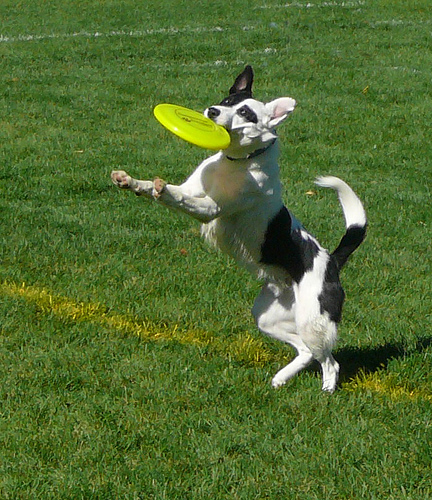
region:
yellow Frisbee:
[143, 77, 226, 149]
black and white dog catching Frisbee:
[145, 59, 391, 374]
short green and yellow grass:
[41, 381, 90, 430]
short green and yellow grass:
[298, 399, 351, 464]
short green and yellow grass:
[370, 442, 397, 469]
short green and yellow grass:
[39, 287, 79, 356]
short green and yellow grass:
[93, 266, 127, 324]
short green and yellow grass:
[149, 308, 194, 372]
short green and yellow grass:
[46, 113, 80, 156]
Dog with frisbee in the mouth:
[163, 67, 369, 389]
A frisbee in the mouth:
[159, 110, 197, 122]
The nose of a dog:
[208, 108, 216, 115]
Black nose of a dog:
[209, 109, 217, 116]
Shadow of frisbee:
[209, 169, 240, 189]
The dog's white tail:
[344, 195, 354, 211]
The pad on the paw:
[156, 180, 161, 189]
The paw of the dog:
[113, 171, 127, 185]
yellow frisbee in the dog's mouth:
[154, 99, 231, 153]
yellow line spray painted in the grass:
[0, 280, 421, 405]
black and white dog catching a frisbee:
[101, 60, 374, 398]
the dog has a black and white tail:
[313, 165, 365, 266]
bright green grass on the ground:
[0, 2, 428, 497]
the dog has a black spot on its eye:
[233, 102, 261, 124]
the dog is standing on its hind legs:
[111, 68, 380, 399]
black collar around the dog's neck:
[213, 133, 280, 159]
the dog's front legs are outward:
[111, 160, 225, 224]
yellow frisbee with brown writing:
[152, 99, 233, 154]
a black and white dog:
[109, 63, 368, 395]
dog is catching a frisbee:
[109, 63, 368, 395]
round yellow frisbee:
[152, 102, 230, 150]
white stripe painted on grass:
[0, 16, 427, 46]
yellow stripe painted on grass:
[2, 277, 428, 407]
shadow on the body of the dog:
[199, 154, 311, 324]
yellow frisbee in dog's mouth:
[109, 64, 368, 394]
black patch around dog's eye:
[234, 103, 259, 124]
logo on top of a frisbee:
[173, 105, 217, 132]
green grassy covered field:
[2, 0, 429, 496]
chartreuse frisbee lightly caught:
[145, 97, 237, 154]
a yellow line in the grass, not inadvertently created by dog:
[0, 253, 429, 417]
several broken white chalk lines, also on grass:
[2, 2, 427, 91]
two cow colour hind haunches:
[232, 261, 354, 348]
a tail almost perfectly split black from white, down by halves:
[309, 167, 376, 277]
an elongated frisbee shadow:
[188, 138, 314, 279]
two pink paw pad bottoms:
[108, 162, 166, 202]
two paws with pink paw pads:
[98, 163, 173, 210]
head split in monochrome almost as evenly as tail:
[179, 57, 300, 174]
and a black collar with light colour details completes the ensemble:
[219, 126, 280, 170]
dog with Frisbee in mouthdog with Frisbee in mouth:
[107, 53, 373, 414]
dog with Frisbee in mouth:
[110, 55, 371, 404]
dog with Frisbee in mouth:
[107, 46, 374, 404]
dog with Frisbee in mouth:
[107, 51, 378, 401]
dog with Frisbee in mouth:
[100, 57, 367, 400]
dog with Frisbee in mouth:
[107, 66, 366, 397]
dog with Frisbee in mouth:
[91, 64, 370, 402]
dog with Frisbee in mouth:
[104, 62, 374, 400]